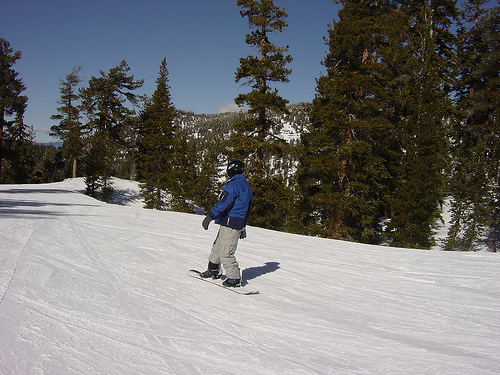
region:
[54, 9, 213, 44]
Clear blue sky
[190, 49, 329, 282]
Person skiing near trees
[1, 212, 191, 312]
Ground covered in snow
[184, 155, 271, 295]
Skier wearing blue jacket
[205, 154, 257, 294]
Skier wearing black helmet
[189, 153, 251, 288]
Skier wearing gray pants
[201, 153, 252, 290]
Skier wearing black boots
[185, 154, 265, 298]
Skier wearing black gloves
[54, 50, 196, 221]
Trees on ground covered in snow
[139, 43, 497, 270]
Person near forest of trees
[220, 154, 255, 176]
man is wearing black helmet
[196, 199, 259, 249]
man is wearing grey gloves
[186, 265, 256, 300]
snowboard is on snow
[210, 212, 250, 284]
mans pants are grey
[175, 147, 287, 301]
snowboarder on snow slope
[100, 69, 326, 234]
trees are lush and abundant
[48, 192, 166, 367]
board tracks are visible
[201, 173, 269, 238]
snow jacket is blue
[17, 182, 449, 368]
snow covers the slope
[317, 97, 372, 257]
tree bark visible through pines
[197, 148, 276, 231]
man is in blue jacket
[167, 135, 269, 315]
man is snowboarding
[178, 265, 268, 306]
snowboard is snow covered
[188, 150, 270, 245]
boarding jacket is blue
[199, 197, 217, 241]
man wearing black gloves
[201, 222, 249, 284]
man is wearing grey pants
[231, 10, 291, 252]
tree is tall and green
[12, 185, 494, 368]
slope is white and snow covered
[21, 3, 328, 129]
sky is clear and blue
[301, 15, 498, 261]
trees are lush and green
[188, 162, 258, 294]
the man is snowboarding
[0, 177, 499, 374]
the ground has snow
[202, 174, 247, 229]
the man has a blue jacket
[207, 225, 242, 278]
the man has gray pants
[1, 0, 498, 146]
the sky is blue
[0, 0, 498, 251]
the trees are tall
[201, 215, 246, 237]
the man has black gloves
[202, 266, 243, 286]
the man has black boots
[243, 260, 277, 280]
the man has a shadow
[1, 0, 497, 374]
the scene takes place outside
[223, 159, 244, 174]
Black helmet the snowboarder is wearing.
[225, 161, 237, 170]
White emblem on the side of the black helmet.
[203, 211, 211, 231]
The left glove on the snowboarder's hand.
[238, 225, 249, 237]
The right glove of the snowboarder's hand.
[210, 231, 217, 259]
The left leg of the snowboarder.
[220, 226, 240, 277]
The right leg of the snowboarder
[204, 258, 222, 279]
The left black boot of the snowboarder.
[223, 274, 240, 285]
The right black boot worn by the snowboarder.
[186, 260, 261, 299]
The snowboard the snowboarder is standing on.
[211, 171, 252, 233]
The blue coat worn by the snowboarder.